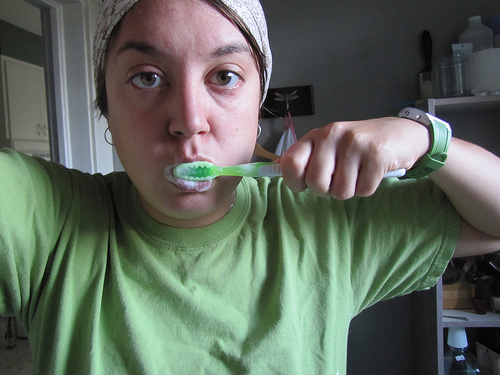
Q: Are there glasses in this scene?
A: No, there are no glasses.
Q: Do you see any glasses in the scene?
A: No, there are no glasses.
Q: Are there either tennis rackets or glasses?
A: No, there are no glasses or tennis rackets.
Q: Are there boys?
A: No, there are no boys.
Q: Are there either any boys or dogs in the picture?
A: No, there are no boys or dogs.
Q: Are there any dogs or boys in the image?
A: No, there are no boys or dogs.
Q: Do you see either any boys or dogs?
A: No, there are no boys or dogs.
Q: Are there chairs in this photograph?
A: No, there are no chairs.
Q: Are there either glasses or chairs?
A: No, there are no chairs or glasses.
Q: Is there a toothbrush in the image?
A: Yes, there is a toothbrush.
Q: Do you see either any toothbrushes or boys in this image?
A: Yes, there is a toothbrush.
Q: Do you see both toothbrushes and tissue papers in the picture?
A: No, there is a toothbrush but no tissues.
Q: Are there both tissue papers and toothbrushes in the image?
A: No, there is a toothbrush but no tissues.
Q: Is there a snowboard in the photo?
A: No, there are no snowboards.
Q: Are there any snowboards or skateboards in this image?
A: No, there are no snowboards or skateboards.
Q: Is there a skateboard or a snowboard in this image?
A: No, there are no snowboards or skateboards.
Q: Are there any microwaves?
A: No, there are no microwaves.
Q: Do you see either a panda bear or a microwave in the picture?
A: No, there are no microwaves or pandas.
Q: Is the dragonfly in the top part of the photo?
A: Yes, the dragonfly is in the top of the image.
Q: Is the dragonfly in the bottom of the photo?
A: No, the dragonfly is in the top of the image.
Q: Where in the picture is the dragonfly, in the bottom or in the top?
A: The dragonfly is in the top of the image.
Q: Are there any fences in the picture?
A: No, there are no fences.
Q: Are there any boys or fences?
A: No, there are no fences or boys.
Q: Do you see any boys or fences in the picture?
A: No, there are no fences or boys.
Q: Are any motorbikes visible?
A: No, there are no motorbikes.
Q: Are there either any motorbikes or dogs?
A: No, there are no motorbikes or dogs.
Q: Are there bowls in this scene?
A: No, there are no bowls.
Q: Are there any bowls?
A: No, there are no bowls.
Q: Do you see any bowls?
A: No, there are no bowls.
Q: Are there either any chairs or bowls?
A: No, there are no bowls or chairs.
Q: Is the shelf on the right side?
A: Yes, the shelf is on the right of the image.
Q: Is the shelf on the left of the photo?
A: No, the shelf is on the right of the image.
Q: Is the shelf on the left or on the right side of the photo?
A: The shelf is on the right of the image.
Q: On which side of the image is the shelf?
A: The shelf is on the right of the image.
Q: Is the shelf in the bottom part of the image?
A: Yes, the shelf is in the bottom of the image.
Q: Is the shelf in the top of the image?
A: No, the shelf is in the bottom of the image.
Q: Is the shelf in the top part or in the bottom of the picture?
A: The shelf is in the bottom of the image.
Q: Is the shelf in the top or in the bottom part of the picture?
A: The shelf is in the bottom of the image.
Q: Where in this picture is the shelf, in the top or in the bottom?
A: The shelf is in the bottom of the image.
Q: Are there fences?
A: No, there are no fences.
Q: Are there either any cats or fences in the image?
A: No, there are no fences or cats.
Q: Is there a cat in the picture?
A: No, there are no cats.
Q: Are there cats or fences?
A: No, there are no cats or fences.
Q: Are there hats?
A: Yes, there is a hat.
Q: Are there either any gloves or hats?
A: Yes, there is a hat.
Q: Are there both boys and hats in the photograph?
A: No, there is a hat but no boys.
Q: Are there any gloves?
A: No, there are no gloves.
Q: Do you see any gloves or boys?
A: No, there are no gloves or boys.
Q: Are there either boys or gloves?
A: No, there are no gloves or boys.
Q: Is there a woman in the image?
A: Yes, there is a woman.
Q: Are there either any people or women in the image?
A: Yes, there is a woman.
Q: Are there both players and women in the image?
A: No, there is a woman but no players.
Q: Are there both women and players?
A: No, there is a woman but no players.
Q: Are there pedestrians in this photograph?
A: No, there are no pedestrians.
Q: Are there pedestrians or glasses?
A: No, there are no pedestrians or glasses.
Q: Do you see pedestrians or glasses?
A: No, there are no pedestrians or glasses.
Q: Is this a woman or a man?
A: This is a woman.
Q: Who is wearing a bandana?
A: The woman is wearing a bandana.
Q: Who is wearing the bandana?
A: The woman is wearing a bandana.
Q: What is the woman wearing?
A: The woman is wearing a bandana.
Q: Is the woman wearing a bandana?
A: Yes, the woman is wearing a bandana.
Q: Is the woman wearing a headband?
A: No, the woman is wearing a bandana.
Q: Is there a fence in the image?
A: No, there are no fences.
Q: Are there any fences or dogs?
A: No, there are no fences or dogs.